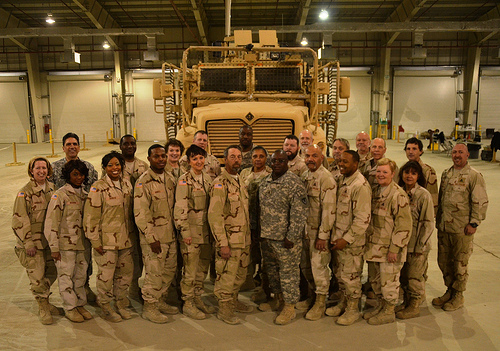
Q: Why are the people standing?
A: Posing.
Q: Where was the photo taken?
A: Hangar.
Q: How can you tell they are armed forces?
A: Uniform.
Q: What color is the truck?
A: Brown.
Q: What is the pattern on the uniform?
A: Camo.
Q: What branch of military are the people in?
A: Army.